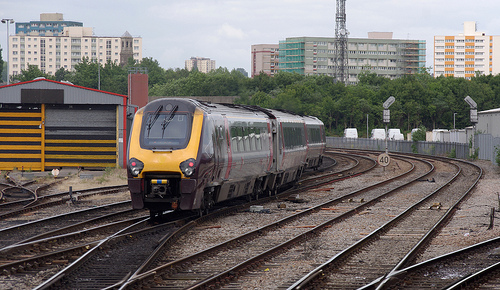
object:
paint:
[131, 108, 204, 175]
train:
[126, 96, 325, 209]